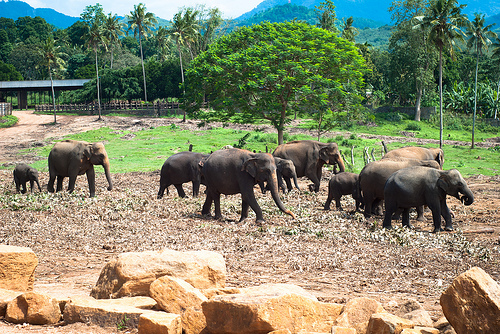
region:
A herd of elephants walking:
[15, 135, 470, 229]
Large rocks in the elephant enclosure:
[1, 240, 478, 332]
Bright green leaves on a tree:
[186, 24, 364, 128]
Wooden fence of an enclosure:
[36, 101, 178, 110]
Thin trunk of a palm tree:
[436, 53, 446, 147]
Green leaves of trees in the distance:
[24, 5, 218, 82]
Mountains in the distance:
[1, 0, 266, 35]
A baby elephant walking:
[12, 162, 39, 190]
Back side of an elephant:
[155, 151, 181, 199]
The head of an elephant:
[443, 166, 476, 206]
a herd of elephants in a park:
[1, 68, 486, 290]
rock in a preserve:
[5, 242, 486, 332]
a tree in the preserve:
[159, 8, 400, 141]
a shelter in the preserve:
[2, 70, 98, 125]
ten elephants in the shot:
[1, 121, 481, 239]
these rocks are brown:
[12, 242, 497, 329]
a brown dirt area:
[19, 105, 114, 129]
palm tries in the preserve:
[78, 1, 165, 126]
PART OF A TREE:
[177, 8, 368, 180]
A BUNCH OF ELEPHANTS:
[6, 120, 478, 235]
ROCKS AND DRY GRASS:
[107, 236, 268, 305]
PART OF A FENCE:
[32, 86, 189, 116]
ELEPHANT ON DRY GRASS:
[180, 144, 310, 244]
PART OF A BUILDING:
[8, 73, 99, 111]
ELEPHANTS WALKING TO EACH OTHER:
[151, 120, 481, 234]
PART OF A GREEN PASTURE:
[125, 141, 182, 163]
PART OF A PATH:
[16, 108, 46, 130]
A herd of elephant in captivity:
[7, 119, 488, 243]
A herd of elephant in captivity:
[7, 132, 477, 246]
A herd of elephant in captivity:
[7, 133, 478, 241]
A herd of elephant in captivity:
[4, 132, 484, 242]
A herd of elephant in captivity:
[2, 138, 474, 239]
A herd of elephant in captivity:
[5, 133, 487, 235]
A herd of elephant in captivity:
[7, 133, 482, 235]